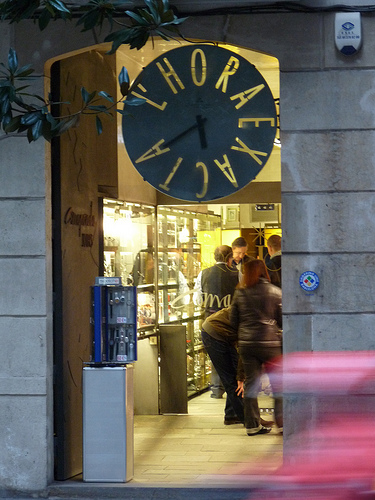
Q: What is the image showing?
A: It is showing a store.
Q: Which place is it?
A: It is a store.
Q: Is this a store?
A: Yes, it is a store.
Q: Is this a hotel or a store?
A: It is a store.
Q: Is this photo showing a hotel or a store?
A: It is showing a store.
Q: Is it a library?
A: No, it is a store.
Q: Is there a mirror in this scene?
A: No, there are no mirrors.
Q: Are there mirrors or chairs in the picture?
A: No, there are no mirrors or chairs.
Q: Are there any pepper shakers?
A: No, there are no pepper shakers.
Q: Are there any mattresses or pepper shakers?
A: No, there are no pepper shakers or mattresses.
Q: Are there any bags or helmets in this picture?
A: No, there are no helmets or bags.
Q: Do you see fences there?
A: No, there are no fences.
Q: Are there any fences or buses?
A: No, there are no fences or buses.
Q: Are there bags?
A: No, there are no bags.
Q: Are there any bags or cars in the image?
A: No, there are no bags or cars.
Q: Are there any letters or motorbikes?
A: Yes, there are letters.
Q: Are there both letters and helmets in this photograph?
A: No, there are letters but no helmets.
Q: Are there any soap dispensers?
A: No, there are no soap dispensers.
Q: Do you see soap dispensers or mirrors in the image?
A: No, there are no soap dispensers or mirrors.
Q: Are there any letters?
A: Yes, there are letters.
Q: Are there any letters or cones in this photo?
A: Yes, there are letters.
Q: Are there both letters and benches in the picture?
A: No, there are letters but no benches.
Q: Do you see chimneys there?
A: No, there are no chimneys.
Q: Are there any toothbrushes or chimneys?
A: No, there are no chimneys or toothbrushes.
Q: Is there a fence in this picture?
A: No, there are no fences.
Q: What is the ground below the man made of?
A: The ground is made of wood.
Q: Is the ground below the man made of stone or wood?
A: The ground is made of wood.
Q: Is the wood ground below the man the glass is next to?
A: Yes, the ground is below the man.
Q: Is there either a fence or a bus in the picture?
A: No, there are no buses or fences.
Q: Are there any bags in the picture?
A: No, there are no bags.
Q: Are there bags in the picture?
A: No, there are no bags.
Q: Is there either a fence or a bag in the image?
A: No, there are no bags or fences.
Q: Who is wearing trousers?
A: The girl is wearing trousers.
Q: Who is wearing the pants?
A: The girl is wearing trousers.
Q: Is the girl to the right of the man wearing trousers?
A: Yes, the girl is wearing trousers.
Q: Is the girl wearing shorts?
A: No, the girl is wearing trousers.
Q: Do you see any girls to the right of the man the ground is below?
A: Yes, there is a girl to the right of the man.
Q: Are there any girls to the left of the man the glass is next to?
A: No, the girl is to the right of the man.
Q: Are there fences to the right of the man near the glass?
A: No, there is a girl to the right of the man.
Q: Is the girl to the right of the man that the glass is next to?
A: Yes, the girl is to the right of the man.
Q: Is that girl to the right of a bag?
A: No, the girl is to the right of the man.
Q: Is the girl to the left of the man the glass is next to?
A: No, the girl is to the right of the man.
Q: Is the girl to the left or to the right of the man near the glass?
A: The girl is to the right of the man.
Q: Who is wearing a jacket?
A: The girl is wearing a jacket.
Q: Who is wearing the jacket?
A: The girl is wearing a jacket.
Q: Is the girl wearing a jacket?
A: Yes, the girl is wearing a jacket.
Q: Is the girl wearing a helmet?
A: No, the girl is wearing a jacket.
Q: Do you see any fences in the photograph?
A: No, there are no fences.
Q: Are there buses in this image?
A: No, there are no buses.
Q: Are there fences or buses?
A: No, there are no buses or fences.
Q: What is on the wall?
A: The sign is on the wall.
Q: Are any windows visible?
A: Yes, there is a window.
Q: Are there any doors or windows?
A: Yes, there is a window.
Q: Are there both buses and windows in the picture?
A: No, there is a window but no buses.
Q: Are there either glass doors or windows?
A: Yes, there is a glass window.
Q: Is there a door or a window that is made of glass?
A: Yes, the window is made of glass.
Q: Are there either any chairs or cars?
A: No, there are no cars or chairs.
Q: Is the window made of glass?
A: Yes, the window is made of glass.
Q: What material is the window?
A: The window is made of glass.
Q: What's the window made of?
A: The window is made of glass.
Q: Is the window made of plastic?
A: No, the window is made of glass.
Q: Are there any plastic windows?
A: No, there is a window but it is made of glass.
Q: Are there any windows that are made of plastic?
A: No, there is a window but it is made of glass.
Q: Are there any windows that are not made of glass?
A: No, there is a window but it is made of glass.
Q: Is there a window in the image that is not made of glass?
A: No, there is a window but it is made of glass.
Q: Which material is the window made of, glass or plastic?
A: The window is made of glass.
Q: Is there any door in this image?
A: Yes, there is a door.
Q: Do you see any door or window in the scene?
A: Yes, there is a door.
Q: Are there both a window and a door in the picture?
A: Yes, there are both a door and a window.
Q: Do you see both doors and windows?
A: Yes, there are both a door and a window.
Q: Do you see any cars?
A: No, there are no cars.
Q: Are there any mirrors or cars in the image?
A: No, there are no cars or mirrors.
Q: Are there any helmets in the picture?
A: No, there are no helmets.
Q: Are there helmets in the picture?
A: No, there are no helmets.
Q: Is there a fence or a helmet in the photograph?
A: No, there are no helmets or fences.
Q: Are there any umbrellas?
A: No, there are no umbrellas.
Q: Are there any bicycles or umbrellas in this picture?
A: No, there are no umbrellas or bicycles.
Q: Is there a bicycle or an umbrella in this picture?
A: No, there are no umbrellas or bicycles.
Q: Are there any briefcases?
A: No, there are no briefcases.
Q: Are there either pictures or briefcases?
A: No, there are no briefcases or pictures.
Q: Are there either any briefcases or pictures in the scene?
A: No, there are no briefcases or pictures.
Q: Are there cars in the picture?
A: No, there are no cars.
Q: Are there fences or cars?
A: No, there are no cars or fences.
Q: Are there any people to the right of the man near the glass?
A: Yes, there is a person to the right of the man.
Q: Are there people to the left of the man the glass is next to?
A: No, the person is to the right of the man.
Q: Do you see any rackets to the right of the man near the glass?
A: No, there is a person to the right of the man.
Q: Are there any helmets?
A: No, there are no helmets.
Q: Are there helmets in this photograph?
A: No, there are no helmets.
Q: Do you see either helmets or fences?
A: No, there are no helmets or fences.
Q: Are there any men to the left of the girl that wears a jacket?
A: Yes, there is a man to the left of the girl.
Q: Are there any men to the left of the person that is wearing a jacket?
A: Yes, there is a man to the left of the girl.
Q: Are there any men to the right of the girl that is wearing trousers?
A: No, the man is to the left of the girl.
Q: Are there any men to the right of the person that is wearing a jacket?
A: No, the man is to the left of the girl.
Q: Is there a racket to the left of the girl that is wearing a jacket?
A: No, there is a man to the left of the girl.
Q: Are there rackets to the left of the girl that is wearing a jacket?
A: No, there is a man to the left of the girl.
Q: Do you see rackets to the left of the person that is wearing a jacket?
A: No, there is a man to the left of the girl.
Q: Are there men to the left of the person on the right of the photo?
A: Yes, there is a man to the left of the person.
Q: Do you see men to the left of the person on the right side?
A: Yes, there is a man to the left of the person.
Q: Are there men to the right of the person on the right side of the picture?
A: No, the man is to the left of the person.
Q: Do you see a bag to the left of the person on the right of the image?
A: No, there is a man to the left of the person.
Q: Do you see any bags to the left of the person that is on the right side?
A: No, there is a man to the left of the person.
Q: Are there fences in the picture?
A: No, there are no fences.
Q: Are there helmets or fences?
A: No, there are no fences or helmets.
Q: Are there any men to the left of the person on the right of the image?
A: Yes, there is a man to the left of the person.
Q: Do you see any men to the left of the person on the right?
A: Yes, there is a man to the left of the person.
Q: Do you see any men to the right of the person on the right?
A: No, the man is to the left of the person.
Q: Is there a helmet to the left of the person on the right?
A: No, there is a man to the left of the person.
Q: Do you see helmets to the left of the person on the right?
A: No, there is a man to the left of the person.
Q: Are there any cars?
A: No, there are no cars.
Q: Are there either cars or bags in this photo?
A: No, there are no cars or bags.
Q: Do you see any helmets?
A: No, there are no helmets.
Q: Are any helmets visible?
A: No, there are no helmets.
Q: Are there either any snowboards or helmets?
A: No, there are no helmets or snowboards.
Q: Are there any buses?
A: No, there are no buses.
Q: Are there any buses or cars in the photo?
A: No, there are no buses or cars.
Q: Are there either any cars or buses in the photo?
A: No, there are no buses or cars.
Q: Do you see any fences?
A: No, there are no fences.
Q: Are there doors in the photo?
A: Yes, there is a door.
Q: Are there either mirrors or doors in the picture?
A: Yes, there is a door.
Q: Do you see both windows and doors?
A: Yes, there are both a door and windows.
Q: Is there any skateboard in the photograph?
A: No, there are no skateboards.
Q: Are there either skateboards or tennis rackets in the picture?
A: No, there are no skateboards or tennis rackets.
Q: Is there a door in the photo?
A: Yes, there are doors.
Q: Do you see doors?
A: Yes, there are doors.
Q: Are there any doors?
A: Yes, there are doors.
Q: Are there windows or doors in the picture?
A: Yes, there are doors.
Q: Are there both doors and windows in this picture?
A: Yes, there are both doors and a window.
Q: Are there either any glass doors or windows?
A: Yes, there are glass doors.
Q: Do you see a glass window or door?
A: Yes, there are glass doors.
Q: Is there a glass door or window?
A: Yes, there are glass doors.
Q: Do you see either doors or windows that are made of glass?
A: Yes, the doors are made of glass.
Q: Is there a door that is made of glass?
A: Yes, there are doors that are made of glass.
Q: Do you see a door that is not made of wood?
A: Yes, there are doors that are made of glass.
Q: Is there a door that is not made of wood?
A: Yes, there are doors that are made of glass.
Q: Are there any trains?
A: No, there are no trains.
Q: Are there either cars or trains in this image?
A: No, there are no trains or cars.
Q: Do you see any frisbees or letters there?
A: Yes, there are letters.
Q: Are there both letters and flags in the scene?
A: No, there are letters but no flags.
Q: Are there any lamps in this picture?
A: No, there are no lamps.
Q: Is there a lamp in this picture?
A: No, there are no lamps.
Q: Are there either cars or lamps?
A: No, there are no lamps or cars.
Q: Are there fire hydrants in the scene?
A: No, there are no fire hydrants.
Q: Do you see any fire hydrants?
A: No, there are no fire hydrants.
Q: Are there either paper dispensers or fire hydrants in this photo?
A: No, there are no fire hydrants or paper dispensers.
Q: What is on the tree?
A: The leaves are on the tree.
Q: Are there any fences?
A: No, there are no fences.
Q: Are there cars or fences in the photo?
A: No, there are no fences or cars.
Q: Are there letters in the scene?
A: Yes, there are letters.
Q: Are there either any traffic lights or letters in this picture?
A: Yes, there are letters.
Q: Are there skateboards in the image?
A: No, there are no skateboards.